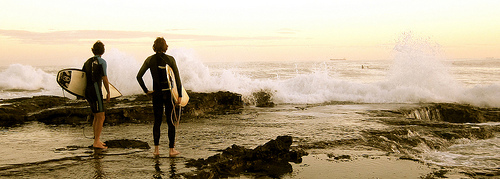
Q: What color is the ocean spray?
A: White.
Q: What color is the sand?
A: Brown.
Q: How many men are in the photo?
A: Two.